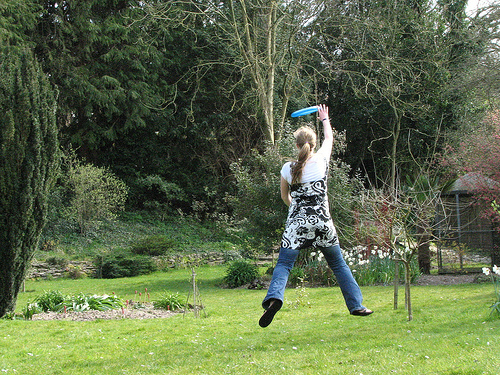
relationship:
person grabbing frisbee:
[257, 102, 375, 329] [289, 103, 321, 120]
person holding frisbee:
[257, 102, 375, 329] [289, 103, 321, 120]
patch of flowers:
[218, 239, 437, 289] [305, 240, 416, 285]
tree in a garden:
[116, 2, 370, 269] [10, 230, 499, 325]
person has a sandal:
[257, 102, 375, 329] [352, 308, 376, 318]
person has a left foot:
[257, 102, 375, 329] [257, 298, 283, 329]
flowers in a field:
[305, 240, 416, 285] [1, 188, 500, 372]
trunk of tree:
[404, 266, 417, 320] [333, 159, 469, 323]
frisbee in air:
[289, 103, 321, 120] [4, 40, 498, 289]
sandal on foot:
[352, 308, 376, 318] [351, 303, 379, 319]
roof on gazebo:
[439, 168, 500, 194] [437, 191, 500, 274]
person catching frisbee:
[257, 102, 375, 329] [289, 103, 321, 120]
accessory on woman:
[322, 116, 331, 121] [257, 102, 375, 329]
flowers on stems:
[305, 240, 416, 285] [491, 274, 500, 310]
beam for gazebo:
[416, 202, 432, 276] [437, 191, 500, 274]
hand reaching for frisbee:
[314, 102, 330, 122] [289, 103, 321, 120]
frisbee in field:
[289, 103, 321, 120] [1, 188, 500, 372]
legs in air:
[257, 243, 376, 328] [4, 40, 498, 289]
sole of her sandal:
[258, 299, 283, 329] [256, 299, 285, 331]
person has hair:
[257, 102, 375, 329] [289, 126, 319, 187]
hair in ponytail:
[289, 126, 319, 187] [290, 142, 312, 187]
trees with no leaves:
[333, 159, 469, 323] [350, 194, 402, 244]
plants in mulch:
[26, 288, 190, 314] [43, 312, 166, 320]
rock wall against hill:
[28, 247, 246, 280] [54, 159, 244, 246]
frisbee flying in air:
[289, 103, 321, 120] [4, 40, 498, 289]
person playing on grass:
[257, 102, 375, 329] [3, 321, 492, 374]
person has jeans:
[257, 102, 375, 329] [260, 244, 368, 315]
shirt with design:
[279, 140, 342, 251] [281, 177, 338, 249]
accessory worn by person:
[322, 116, 331, 121] [257, 102, 375, 329]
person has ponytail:
[257, 102, 375, 329] [290, 142, 312, 187]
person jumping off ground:
[257, 102, 375, 329] [3, 270, 499, 372]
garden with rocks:
[10, 230, 499, 325] [425, 276, 478, 286]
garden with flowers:
[10, 230, 499, 325] [305, 240, 416, 285]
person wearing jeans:
[257, 102, 375, 329] [260, 244, 368, 315]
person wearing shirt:
[257, 102, 375, 329] [279, 140, 342, 251]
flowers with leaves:
[305, 240, 416, 285] [362, 267, 416, 284]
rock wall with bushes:
[28, 247, 246, 280] [99, 236, 173, 280]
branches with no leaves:
[369, 201, 400, 253] [350, 194, 402, 244]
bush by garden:
[220, 259, 259, 289] [10, 230, 499, 325]